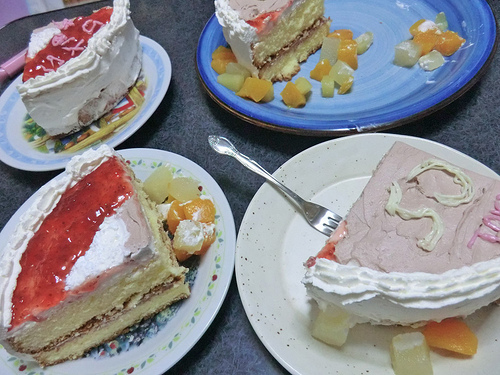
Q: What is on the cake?
A: Red sauce.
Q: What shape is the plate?
A: Round.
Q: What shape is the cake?
A: Triangle.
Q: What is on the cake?
A: Pink icing.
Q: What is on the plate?
A: Blue border.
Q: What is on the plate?
A: Fruit.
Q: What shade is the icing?
A: White.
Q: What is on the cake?
A: Icing.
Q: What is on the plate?
A: A fork.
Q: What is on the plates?
A: Cake.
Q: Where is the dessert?
A: On the plates.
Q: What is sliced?
A: Cake.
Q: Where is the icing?
A: On the cake.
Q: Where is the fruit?
A: On the plates.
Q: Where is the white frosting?
A: On the cake.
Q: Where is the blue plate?
A: On the table.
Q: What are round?
A: The plates.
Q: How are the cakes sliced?
A: Large.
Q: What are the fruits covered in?
A: Whipped cream?.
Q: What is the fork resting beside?
A: Piece of cake.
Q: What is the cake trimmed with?
A: White frosting.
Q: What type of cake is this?
A: Yellow cake.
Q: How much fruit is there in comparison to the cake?
A: Less fruit.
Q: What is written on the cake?
A: 50.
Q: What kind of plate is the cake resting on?
A: Circular plate.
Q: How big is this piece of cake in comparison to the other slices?
A: About the same size.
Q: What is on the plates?
A: Food.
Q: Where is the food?
A: On the plates.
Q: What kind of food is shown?
A: Desserts.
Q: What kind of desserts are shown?
A: Cake.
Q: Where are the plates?
A: On the table.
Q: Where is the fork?
A: On the plate.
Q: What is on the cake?
A: Frosting.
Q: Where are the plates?
A: On the table.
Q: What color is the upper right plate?
A: Blue.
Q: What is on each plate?
A: A piece of cake.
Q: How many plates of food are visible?
A: Four.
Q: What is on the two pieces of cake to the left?
A: Strawberry glaze.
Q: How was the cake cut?
A: Into quarters.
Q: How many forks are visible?
A: One.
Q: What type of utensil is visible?
A: A fork.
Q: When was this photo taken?
A: During a mealtime.